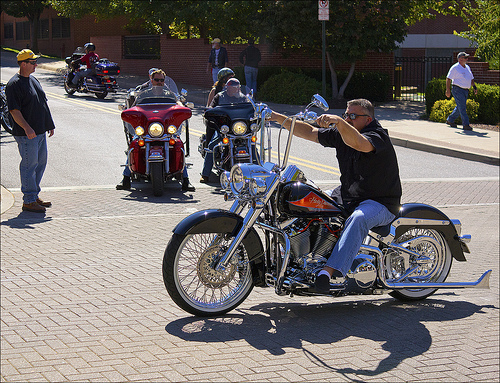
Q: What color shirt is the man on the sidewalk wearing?
A: White.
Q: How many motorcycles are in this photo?
A: Five.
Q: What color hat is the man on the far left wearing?
A: Yellow.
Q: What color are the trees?
A: Green.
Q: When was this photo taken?
A: Daytime.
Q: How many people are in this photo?
A: Ten.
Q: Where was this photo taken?
A: Plaza.